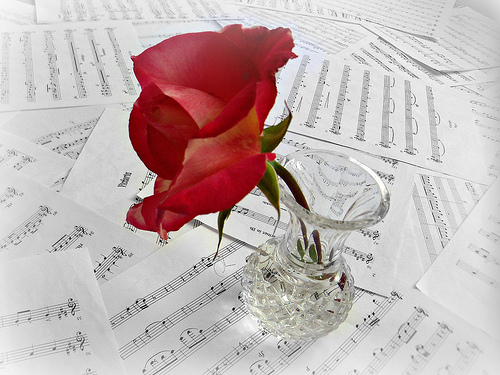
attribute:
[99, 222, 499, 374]
paper — white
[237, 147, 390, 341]
vase — half filled, diamond-pattern, glass, clear, Red, crystal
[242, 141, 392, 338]
urn — clear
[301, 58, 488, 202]
writing — black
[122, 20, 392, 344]
rose — Red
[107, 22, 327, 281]
rose — red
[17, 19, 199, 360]
sheets — scattered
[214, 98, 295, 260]
leaves — green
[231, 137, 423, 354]
vase — open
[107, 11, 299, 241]
flower — red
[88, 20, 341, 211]
rose — red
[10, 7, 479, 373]
music sheets — white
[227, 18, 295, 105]
edge — uneven